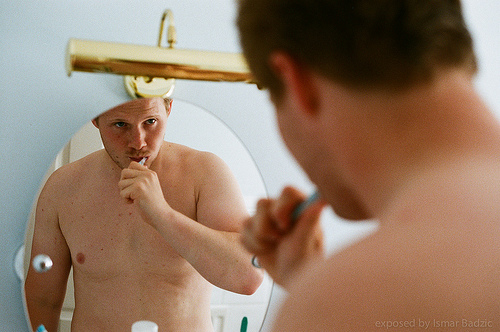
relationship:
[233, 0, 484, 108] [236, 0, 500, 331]
hair on guy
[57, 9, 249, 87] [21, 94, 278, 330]
light over mirror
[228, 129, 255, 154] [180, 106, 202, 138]
edge of mirror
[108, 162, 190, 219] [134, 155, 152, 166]
hand holding toothbrush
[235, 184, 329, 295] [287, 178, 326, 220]
hand holding toothbrush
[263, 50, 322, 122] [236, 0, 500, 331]
ear of guy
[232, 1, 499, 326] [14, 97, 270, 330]
man looking at man's reflection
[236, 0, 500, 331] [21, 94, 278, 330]
guy looking in mirror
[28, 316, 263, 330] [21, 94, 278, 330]
objects near mirror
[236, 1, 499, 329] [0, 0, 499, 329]
guy in bathroom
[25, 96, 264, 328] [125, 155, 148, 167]
man reflection brushing teeth